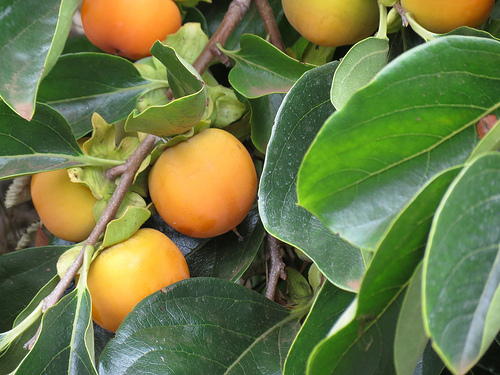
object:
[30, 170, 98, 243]
fruit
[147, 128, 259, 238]
fruit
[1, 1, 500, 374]
tree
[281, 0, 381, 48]
fruit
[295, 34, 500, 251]
leaf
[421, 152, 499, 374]
leaf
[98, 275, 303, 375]
leaf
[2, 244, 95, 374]
leaves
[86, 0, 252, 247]
branch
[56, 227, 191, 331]
fruits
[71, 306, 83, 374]
reflection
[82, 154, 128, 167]
stem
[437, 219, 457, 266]
back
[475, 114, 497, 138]
spot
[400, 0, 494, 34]
pear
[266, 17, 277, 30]
brown